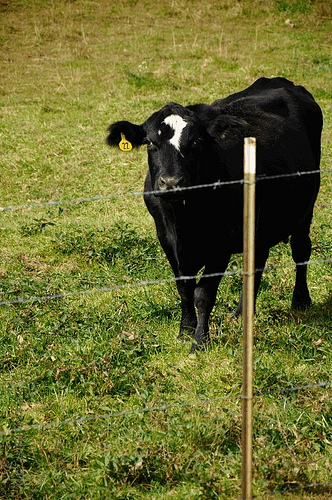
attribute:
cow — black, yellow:
[89, 88, 330, 346]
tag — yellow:
[121, 121, 138, 158]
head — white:
[145, 97, 199, 178]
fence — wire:
[13, 162, 138, 451]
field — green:
[31, 152, 92, 181]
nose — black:
[144, 174, 187, 203]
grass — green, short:
[38, 75, 82, 103]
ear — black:
[98, 121, 124, 139]